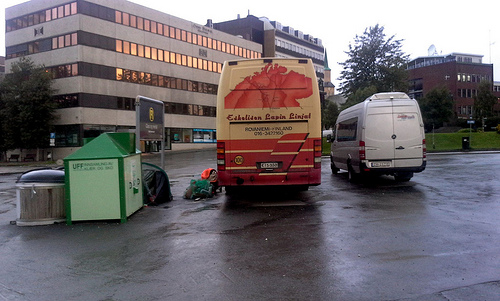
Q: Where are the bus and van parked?
A: In front of the white building.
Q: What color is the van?
A: White.